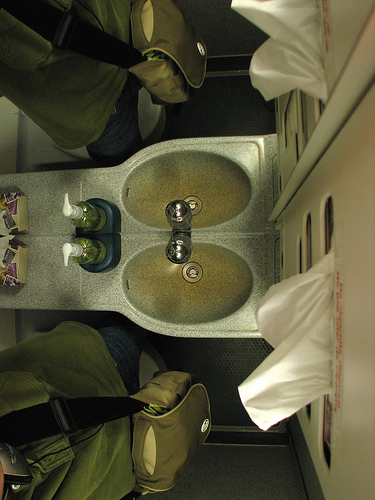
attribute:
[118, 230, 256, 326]
sink — small, round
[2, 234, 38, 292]
box — small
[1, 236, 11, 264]
paper towels — square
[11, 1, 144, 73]
shoulder strap — black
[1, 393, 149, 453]
strap — black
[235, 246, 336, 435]
towel — large, white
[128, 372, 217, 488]
pack — tan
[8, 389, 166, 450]
strap — long, black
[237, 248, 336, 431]
tissue paper — white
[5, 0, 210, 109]
backpack — brown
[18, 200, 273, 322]
water faucet — chrome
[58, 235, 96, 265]
bottle — small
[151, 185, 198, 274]
faucet — silver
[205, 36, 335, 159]
tissues — sticking out